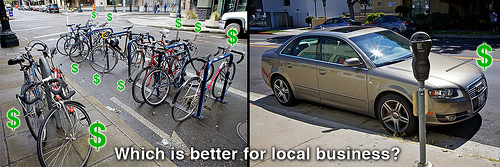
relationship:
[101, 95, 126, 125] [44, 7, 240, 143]
trash laying on street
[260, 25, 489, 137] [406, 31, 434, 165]
gold car parked next to parking meter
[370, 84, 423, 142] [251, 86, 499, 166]
wheel at curb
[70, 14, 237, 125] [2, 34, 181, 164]
bicycles at curb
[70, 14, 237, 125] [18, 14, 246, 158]
bicycles at street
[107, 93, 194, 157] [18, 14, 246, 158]
arrow painted on street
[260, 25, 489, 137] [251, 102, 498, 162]
gold car parked at curb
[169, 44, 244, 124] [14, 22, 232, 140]
bicycle parked at racks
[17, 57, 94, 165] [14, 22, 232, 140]
bicycle parked at racks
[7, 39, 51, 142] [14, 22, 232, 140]
bicycle parked at racks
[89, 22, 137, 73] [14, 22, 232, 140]
bicycle parked at racks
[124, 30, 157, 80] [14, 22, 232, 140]
bicycle parked at racks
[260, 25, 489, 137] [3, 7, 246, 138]
gold car parked beside street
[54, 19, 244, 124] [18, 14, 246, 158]
bikes parked beside street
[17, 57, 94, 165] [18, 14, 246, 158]
bicycle parked beside street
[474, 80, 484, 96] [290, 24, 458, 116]
company emblem on front car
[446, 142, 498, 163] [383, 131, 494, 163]
grass growing in sidewalk's crack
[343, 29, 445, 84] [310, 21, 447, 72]
sun reflected on windshield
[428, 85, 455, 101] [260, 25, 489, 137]
headlight on gold car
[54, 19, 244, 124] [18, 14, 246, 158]
bikes parked by street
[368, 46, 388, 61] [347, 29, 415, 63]
sun reflecting on windshield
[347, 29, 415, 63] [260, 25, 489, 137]
windshield on gold car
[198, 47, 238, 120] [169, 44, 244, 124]
guard rail for bicycle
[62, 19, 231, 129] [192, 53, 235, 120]
bicycles locked in guard rail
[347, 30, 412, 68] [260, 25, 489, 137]
windshield of gold car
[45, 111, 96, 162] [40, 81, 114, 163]
spokes of wheel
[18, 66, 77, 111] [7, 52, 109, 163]
handlebars of bicycle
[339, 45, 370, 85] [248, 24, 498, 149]
rear mirror of car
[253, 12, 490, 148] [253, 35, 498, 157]
gold car parked on street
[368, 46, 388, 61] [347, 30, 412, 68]
sun on windshield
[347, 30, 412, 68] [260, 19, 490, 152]
windshield of car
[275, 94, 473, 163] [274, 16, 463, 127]
shadow of car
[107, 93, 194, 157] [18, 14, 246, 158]
arrow on street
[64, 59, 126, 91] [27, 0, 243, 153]
dollar signs with street